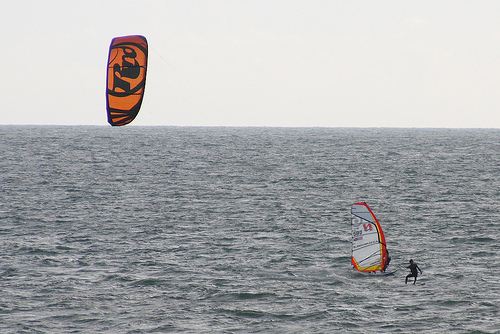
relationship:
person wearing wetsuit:
[403, 256, 424, 286] [402, 262, 423, 283]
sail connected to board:
[348, 198, 392, 278] [354, 269, 395, 280]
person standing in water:
[403, 256, 424, 286] [1, 123, 499, 332]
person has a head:
[403, 256, 424, 286] [409, 255, 415, 266]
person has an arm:
[403, 256, 424, 286] [415, 262, 426, 277]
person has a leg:
[403, 256, 424, 286] [403, 269, 412, 284]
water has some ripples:
[1, 123, 499, 332] [2, 123, 498, 333]